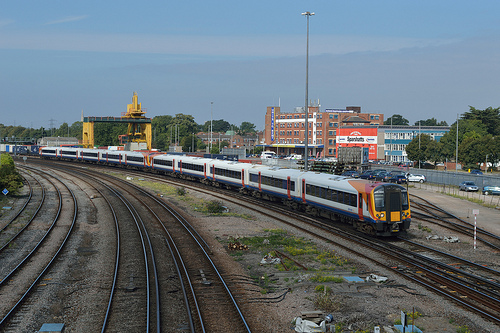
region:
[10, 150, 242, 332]
group of railroads on ground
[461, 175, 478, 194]
a silver sedan car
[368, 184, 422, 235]
front of a train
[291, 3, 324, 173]
a tall lamp post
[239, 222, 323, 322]
the land between 2 railroads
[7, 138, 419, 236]
a train of railroad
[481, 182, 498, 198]
car parked in front of silver sedan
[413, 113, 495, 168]
trees next to some buildings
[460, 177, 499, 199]
2 cars parked on street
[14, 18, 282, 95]
a blue cloudy sky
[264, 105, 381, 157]
long white anmultistory brick buildingd yellow train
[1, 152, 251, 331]
five sets of train tracks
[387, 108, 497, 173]
trees with green foliage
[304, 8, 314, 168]
light on stanchion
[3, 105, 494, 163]
clusters of trees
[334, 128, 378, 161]
large red and yellow advertising sign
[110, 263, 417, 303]
train track switching mechanism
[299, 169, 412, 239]
train engine painted white, blue, yellow red and orange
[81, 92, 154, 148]
large crane a rail support equipment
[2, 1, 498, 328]
passenger train passing through railyard of small town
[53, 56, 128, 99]
this is the sky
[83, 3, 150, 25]
the sky is blue in color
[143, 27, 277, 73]
the sky has some clouds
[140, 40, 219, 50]
the clouds are white in color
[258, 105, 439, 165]
these are some buildings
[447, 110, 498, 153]
these are some trees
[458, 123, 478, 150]
the leaves are green in color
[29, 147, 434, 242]
this is a train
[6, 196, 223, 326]
these are some railway lines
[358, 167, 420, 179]
these are some cars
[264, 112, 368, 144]
a large brown house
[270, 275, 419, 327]
litter between the railway lines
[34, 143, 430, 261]
a long white train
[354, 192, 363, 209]
the door is shut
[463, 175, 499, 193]
cars are parked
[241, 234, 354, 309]
grass is scatterly growing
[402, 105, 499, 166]
a large green tree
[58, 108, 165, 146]
a green and yellow tower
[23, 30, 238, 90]
the skt is clear no clouds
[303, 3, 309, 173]
a large signpost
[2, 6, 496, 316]
a scene at the downtown area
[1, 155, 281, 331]
rows of tracks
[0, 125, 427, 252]
a white and blue train on track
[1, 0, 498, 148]
a sky with little clouds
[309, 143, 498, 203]
some cars in a parking lot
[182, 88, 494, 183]
some buildings in the background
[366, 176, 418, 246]
a yellow front of a train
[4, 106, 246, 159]
green trees in the background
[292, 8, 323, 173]
a tall gray pole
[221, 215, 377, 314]
green patch of grass